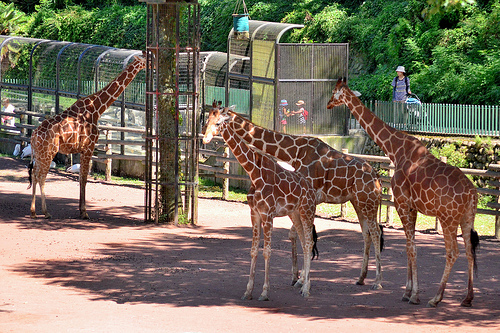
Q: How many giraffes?
A: 4.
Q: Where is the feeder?
A: Hanging from the tree in the middle of the enclosure.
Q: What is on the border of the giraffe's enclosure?
A: A wooden fence.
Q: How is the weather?
A: Sunny.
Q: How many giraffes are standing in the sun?
A: 0.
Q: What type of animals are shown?
A: Giraffes.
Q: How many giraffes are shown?
A: 4.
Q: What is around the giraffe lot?
A: Fence.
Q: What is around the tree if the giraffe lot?
A: Fence.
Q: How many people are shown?
A: 4.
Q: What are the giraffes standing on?
A: Dirt.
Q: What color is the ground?
A: Brown.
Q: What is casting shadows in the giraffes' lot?
A: Trees.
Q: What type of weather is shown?
A: Clear and sunny.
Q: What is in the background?
A: Trees.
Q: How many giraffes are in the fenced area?
A: 4.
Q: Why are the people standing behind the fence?
A: To observe the giraffes.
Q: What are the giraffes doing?
A: Standing under trees for shade.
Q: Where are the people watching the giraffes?
A: The zoo.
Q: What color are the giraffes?
A: Brown and white.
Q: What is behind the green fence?
A: Trees.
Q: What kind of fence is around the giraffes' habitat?
A: Wood and metal.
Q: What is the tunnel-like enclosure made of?
A: Metal wire.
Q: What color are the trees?
A: Green.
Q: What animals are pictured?
A: Giraffes.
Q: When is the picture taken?
A: Daytime.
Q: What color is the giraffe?
A: Brown.